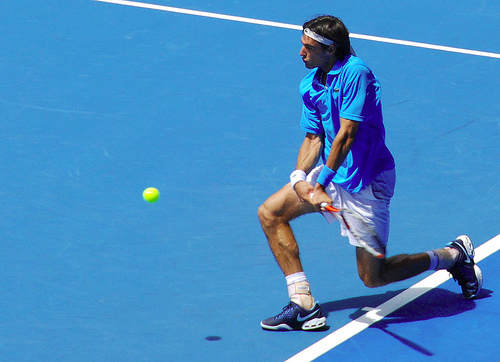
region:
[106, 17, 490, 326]
man is playing tennis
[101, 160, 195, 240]
the ball is lime green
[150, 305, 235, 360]
shadow of the ball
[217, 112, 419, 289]
man is holding a racket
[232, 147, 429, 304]
man is wearing shorts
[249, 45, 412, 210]
man is wearing a blue shirt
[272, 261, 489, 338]
shadow of the player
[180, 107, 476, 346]
man is bending his knees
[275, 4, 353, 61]
man is wearing a headband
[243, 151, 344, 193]
the man is wearing wrist bands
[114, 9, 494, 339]
a man playing tennis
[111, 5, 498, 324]
a tennis player hitting the ball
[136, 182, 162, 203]
a yellow tennis racket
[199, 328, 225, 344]
the shadow of a tennis racket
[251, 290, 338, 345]
a blue and white tennis shoe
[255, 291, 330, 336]
a shoe with a Nike symbol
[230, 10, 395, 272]
a man hitting a backhand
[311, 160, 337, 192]
a blue tennis wristband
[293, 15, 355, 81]
a man wearing a headband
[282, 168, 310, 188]
a white tennis wristband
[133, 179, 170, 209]
the green tennis ball in the air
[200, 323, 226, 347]
the balls shadow on the blue court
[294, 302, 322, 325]
The blue niki logo on the shoe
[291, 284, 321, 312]
The brace on the mans ankle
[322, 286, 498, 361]
The shadw of the tennis player on the court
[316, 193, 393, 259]
The tennis red racquet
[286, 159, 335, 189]
The bands on the mans wrist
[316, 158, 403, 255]
The shorts on the tennis player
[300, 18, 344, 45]
The white band on the mans head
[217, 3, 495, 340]
tennis player lunging for the ball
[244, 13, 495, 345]
This is a man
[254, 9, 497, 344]
This is a man in blue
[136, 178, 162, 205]
This is a ball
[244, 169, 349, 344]
Leg of a man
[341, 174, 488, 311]
Leg of a man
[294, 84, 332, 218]
Hand of a man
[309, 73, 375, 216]
Hand of a man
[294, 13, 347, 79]
Head of a man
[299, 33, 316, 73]
Face of a man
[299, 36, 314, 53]
Eye of a man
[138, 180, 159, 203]
green tennis ball in mid air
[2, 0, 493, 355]
blue floor of tennis court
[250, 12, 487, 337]
man swinging tennis racket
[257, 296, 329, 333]
blue and white Nike sneaker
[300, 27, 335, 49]
white sweat band on head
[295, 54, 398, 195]
sky blue short sleeve shirt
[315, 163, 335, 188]
blue sweat band on wrist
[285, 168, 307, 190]
white sweat band on wrist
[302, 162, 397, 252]
pair of white shorts with pocket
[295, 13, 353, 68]
man with black hair